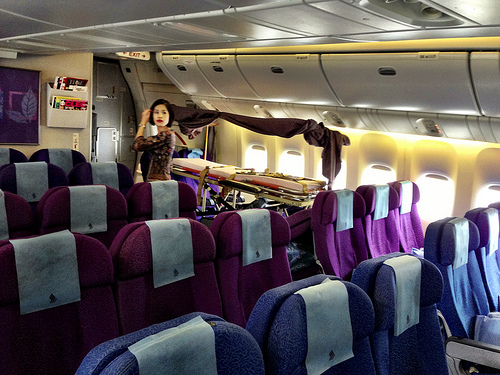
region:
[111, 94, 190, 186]
Asian woman on airplane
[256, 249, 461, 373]
blue airplane seat backs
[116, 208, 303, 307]
pink airplane seat backs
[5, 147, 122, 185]
purple airplane seat backs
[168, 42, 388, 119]
over head storage on airplane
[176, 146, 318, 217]
stretcher on an airplane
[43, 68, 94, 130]
magazine in a rack on the wall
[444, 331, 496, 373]
arm rest on the seat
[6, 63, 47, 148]
purple painting on the wall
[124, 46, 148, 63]
small exit sign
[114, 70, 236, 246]
A woman inside a plane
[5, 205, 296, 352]
A row of red chairs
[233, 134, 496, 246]
Windows on side of the plane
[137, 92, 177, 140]
Woman has black hair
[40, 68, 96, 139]
Magazines on the wall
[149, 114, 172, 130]
Woman wearing red lipstick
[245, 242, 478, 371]
Two blue chairs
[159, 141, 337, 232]
A medical bed on the plane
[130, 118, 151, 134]
A watch around woman's wrist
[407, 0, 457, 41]
A light on the plane's ceiling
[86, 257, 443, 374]
row of three blue airplane seats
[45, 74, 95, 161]
magazine rack on wall of airplane cabin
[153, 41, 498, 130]
over head compartments in airplane cabin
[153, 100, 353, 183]
brown curtain hanging in airplane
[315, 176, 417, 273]
row of three purple airplane seats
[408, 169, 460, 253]
window inside of airplane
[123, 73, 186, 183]
dark haired woman standing in cabin of airplane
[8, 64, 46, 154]
artistic leaves on painting in airplane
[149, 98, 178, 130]
dark haired woman with short cut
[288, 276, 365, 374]
headrest cover on airplane seat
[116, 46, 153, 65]
Overhead exit sign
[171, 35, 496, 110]
Overhead compartments on plane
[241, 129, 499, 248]
Airplane windows from the inside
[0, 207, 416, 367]
Red and blue airplane passenger seats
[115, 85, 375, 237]
Woman standing in an airplane aisle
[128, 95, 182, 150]
Lady with silver colored watch on left wrist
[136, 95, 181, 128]
Lady stroking her hair with her left hand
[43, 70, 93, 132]
Hanging organizer on the wall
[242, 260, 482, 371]
Headrest covers on airplane seats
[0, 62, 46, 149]
Decorative leaf art hanging on the wall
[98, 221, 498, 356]
The chairs are blue.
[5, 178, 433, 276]
The chairs are purple.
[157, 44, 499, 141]
The over head compartment is closed.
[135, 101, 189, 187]
She is standing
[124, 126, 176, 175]
she is wearing a brown dress.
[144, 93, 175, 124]
she has black hair.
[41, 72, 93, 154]
The compartment has magazines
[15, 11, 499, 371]
She is on a plane.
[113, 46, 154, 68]
The exit sign is lit.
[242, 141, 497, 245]
The sun is shining through the windows.